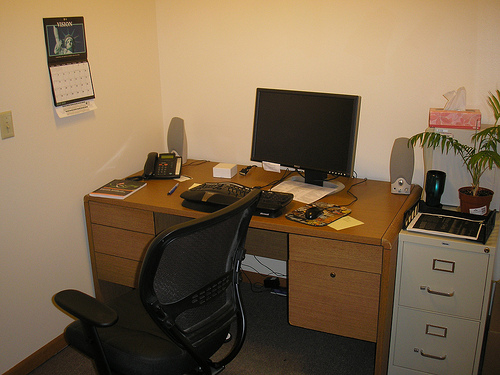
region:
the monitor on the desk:
[248, 81, 361, 182]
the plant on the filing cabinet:
[419, 113, 499, 220]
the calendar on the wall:
[36, 11, 114, 128]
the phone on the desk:
[135, 140, 180, 182]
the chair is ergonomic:
[48, 198, 265, 369]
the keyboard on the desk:
[196, 175, 288, 214]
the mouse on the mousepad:
[297, 198, 330, 225]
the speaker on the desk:
[165, 118, 196, 165]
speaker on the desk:
[381, 127, 411, 199]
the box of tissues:
[417, 88, 488, 135]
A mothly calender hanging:
[35, 17, 107, 115]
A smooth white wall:
[19, 169, 79, 263]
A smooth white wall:
[94, 23, 154, 124]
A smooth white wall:
[159, 18, 236, 94]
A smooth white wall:
[229, 10, 306, 50]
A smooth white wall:
[332, 4, 464, 58]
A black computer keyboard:
[182, 182, 297, 210]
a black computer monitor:
[249, 86, 361, 180]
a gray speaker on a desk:
[390, 135, 415, 197]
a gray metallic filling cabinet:
[389, 211, 499, 373]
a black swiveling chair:
[53, 186, 243, 373]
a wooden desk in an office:
[83, 154, 421, 374]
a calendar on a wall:
[42, 15, 99, 120]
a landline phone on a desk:
[143, 149, 181, 181]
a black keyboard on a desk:
[180, 179, 293, 215]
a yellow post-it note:
[328, 214, 362, 231]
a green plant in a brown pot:
[408, 90, 498, 219]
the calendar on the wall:
[42, 15, 97, 118]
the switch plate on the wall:
[1, 111, 13, 140]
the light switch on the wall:
[4, 120, 10, 131]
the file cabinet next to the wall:
[387, 210, 498, 373]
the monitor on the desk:
[250, 86, 361, 192]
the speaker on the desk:
[390, 135, 415, 194]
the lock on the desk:
[329, 271, 336, 278]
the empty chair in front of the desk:
[53, 187, 259, 372]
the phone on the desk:
[122, 152, 182, 185]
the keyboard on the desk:
[180, 180, 292, 215]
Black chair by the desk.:
[54, 190, 259, 371]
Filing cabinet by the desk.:
[385, 194, 492, 374]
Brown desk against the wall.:
[84, 153, 420, 368]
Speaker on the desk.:
[384, 132, 416, 197]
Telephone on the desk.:
[122, 145, 187, 182]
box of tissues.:
[425, 101, 485, 132]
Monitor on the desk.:
[241, 75, 362, 190]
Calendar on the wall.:
[36, 15, 103, 120]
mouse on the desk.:
[300, 200, 321, 224]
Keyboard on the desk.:
[178, 171, 297, 217]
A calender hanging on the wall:
[40, 8, 108, 126]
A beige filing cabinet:
[387, 228, 488, 370]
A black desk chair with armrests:
[55, 214, 263, 374]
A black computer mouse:
[297, 200, 324, 220]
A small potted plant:
[401, 94, 498, 211]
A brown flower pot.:
[455, 185, 493, 215]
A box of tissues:
[427, 94, 491, 134]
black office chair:
[51, 188, 261, 369]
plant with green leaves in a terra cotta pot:
[407, 88, 498, 217]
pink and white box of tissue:
[428, 83, 480, 129]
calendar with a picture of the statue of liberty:
[43, 14, 97, 118]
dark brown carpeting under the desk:
[23, 283, 377, 370]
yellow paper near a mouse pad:
[329, 213, 362, 230]